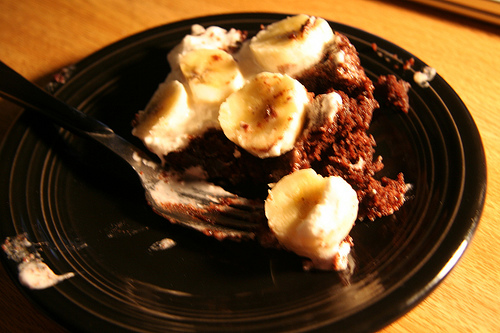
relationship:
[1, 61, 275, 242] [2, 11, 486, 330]
fork on a plate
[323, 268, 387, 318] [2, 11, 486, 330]
reflection on plate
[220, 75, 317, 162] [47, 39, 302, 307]
banana on a plate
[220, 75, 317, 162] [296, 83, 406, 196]
banana and cake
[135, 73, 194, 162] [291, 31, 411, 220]
banana and cake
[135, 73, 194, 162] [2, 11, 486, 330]
banana on a plate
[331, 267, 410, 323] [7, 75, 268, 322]
light hitting plate